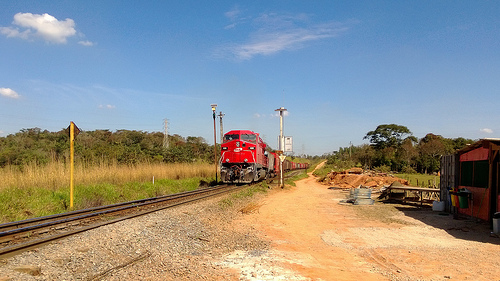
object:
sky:
[1, 0, 497, 155]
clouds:
[11, 11, 78, 46]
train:
[219, 129, 310, 183]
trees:
[360, 125, 419, 163]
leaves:
[387, 151, 395, 158]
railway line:
[0, 181, 237, 256]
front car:
[219, 128, 264, 184]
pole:
[69, 120, 74, 210]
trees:
[14, 126, 47, 171]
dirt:
[234, 166, 495, 281]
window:
[240, 134, 254, 140]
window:
[226, 135, 238, 141]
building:
[450, 138, 498, 221]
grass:
[1, 161, 217, 223]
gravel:
[0, 203, 262, 280]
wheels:
[223, 166, 260, 183]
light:
[222, 146, 227, 149]